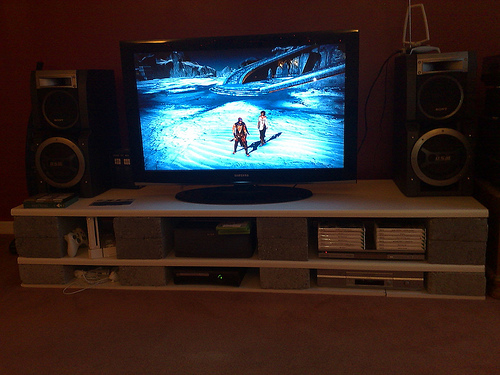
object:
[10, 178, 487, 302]
cabinet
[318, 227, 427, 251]
dvds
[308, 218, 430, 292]
video game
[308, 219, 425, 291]
shelf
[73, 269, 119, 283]
controllers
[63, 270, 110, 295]
wires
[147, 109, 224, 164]
snow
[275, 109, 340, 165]
snow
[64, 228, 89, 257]
controller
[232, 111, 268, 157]
characters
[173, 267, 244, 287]
game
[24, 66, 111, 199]
frame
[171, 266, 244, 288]
xbox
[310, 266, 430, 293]
cuby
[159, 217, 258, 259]
cuby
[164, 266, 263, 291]
cuby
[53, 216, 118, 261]
cuby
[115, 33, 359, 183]
flat screen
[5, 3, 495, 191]
wall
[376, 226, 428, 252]
wine bottle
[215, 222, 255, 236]
video games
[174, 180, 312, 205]
tv stand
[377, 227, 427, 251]
cd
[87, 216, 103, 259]
wii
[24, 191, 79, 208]
dvd cases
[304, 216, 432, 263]
cubby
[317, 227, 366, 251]
cd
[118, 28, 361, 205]
television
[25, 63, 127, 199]
speaker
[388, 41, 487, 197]
speaker